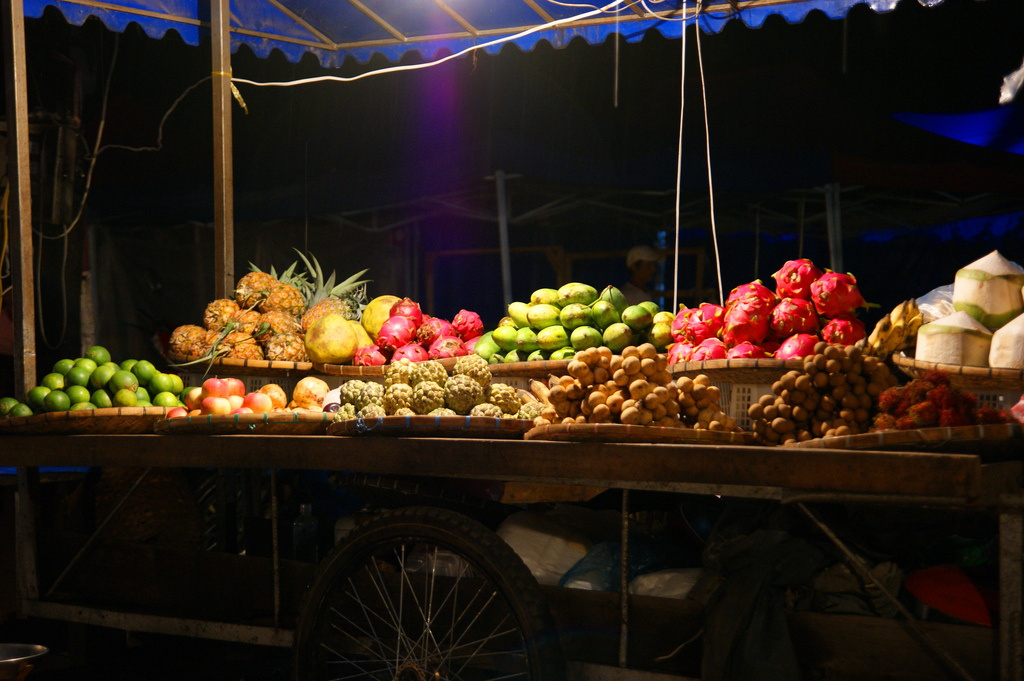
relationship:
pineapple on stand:
[383, 350, 567, 414] [193, 279, 994, 461]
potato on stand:
[594, 331, 760, 453] [2, 221, 761, 453]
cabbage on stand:
[329, 293, 470, 373] [21, 293, 1008, 461]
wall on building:
[386, 187, 508, 280] [72, 47, 1015, 477]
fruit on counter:
[272, 333, 693, 441] [218, 297, 931, 506]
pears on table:
[35, 360, 165, 415] [35, 262, 988, 415]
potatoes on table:
[726, 354, 961, 444] [5, 343, 995, 674]